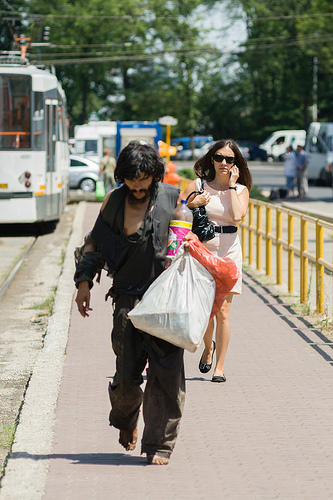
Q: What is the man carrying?
A: A trash bag.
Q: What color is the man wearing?
A: Black.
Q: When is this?
A: Daytime.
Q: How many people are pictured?
A: Two.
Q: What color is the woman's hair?
A: Brown.